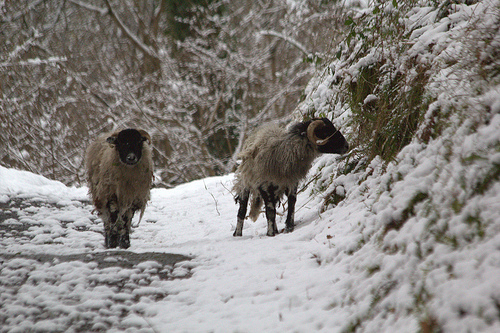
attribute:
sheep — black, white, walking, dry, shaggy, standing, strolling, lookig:
[82, 117, 351, 250]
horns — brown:
[102, 121, 342, 148]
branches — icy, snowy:
[1, 2, 367, 189]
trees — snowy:
[0, 2, 354, 186]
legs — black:
[232, 185, 300, 235]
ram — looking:
[234, 117, 348, 238]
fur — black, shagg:
[309, 118, 352, 157]